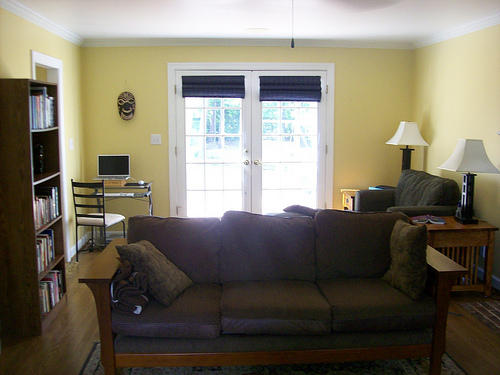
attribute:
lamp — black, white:
[437, 136, 499, 227]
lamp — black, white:
[387, 120, 430, 180]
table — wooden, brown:
[340, 187, 359, 211]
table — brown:
[408, 213, 498, 299]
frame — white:
[30, 47, 71, 263]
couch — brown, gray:
[76, 215, 470, 373]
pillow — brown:
[383, 220, 430, 301]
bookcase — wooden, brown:
[2, 78, 71, 341]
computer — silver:
[93, 154, 131, 184]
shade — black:
[185, 73, 247, 100]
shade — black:
[258, 76, 322, 102]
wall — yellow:
[83, 46, 427, 232]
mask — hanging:
[117, 88, 136, 123]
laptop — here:
[93, 153, 133, 183]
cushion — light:
[80, 213, 126, 227]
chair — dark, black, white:
[71, 180, 129, 265]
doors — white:
[174, 66, 329, 221]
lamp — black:
[454, 174, 484, 226]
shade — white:
[386, 120, 430, 150]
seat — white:
[79, 215, 126, 228]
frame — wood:
[79, 235, 468, 374]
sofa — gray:
[79, 205, 468, 374]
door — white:
[172, 67, 254, 220]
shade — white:
[438, 137, 500, 177]